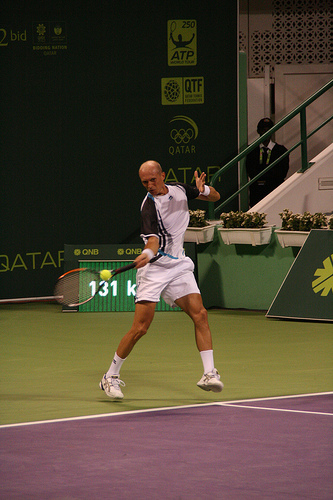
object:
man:
[99, 160, 224, 400]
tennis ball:
[100, 269, 112, 281]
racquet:
[53, 257, 146, 308]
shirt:
[140, 182, 200, 270]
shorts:
[134, 257, 201, 309]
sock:
[199, 350, 214, 375]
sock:
[105, 352, 126, 379]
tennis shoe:
[197, 371, 224, 394]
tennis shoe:
[99, 373, 124, 399]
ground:
[2, 306, 332, 500]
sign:
[73, 248, 99, 256]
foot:
[196, 375, 222, 394]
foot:
[99, 377, 124, 399]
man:
[245, 117, 290, 208]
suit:
[246, 140, 291, 208]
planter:
[181, 223, 215, 244]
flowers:
[185, 208, 207, 226]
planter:
[218, 225, 272, 248]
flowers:
[220, 210, 268, 229]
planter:
[274, 229, 310, 249]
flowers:
[279, 206, 333, 231]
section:
[2, 295, 333, 439]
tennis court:
[0, 297, 333, 500]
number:
[90, 280, 118, 297]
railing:
[208, 77, 333, 223]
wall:
[0, 1, 135, 202]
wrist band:
[200, 185, 211, 197]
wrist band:
[142, 248, 154, 260]